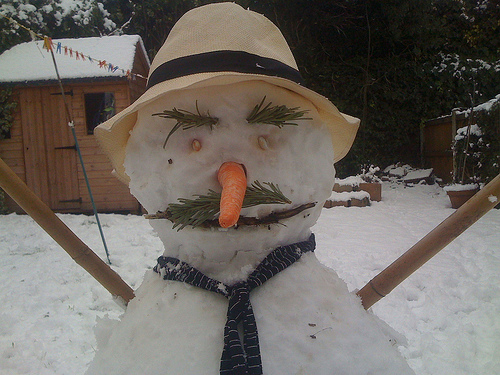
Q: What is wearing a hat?
A: Snowman.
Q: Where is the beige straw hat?
A: Atop the snowman.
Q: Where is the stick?
A: Right side of snowman.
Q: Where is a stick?
A: Left side of snowman.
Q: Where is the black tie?
A: On snowman.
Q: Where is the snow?
A: On building roof.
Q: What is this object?
A: Snowman.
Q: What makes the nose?
A: Carrot.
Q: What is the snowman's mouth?
A: A stick.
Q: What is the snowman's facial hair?
A: Pines.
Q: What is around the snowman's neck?
A: Tie.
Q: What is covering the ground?
A: Snow.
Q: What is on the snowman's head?
A: Hat.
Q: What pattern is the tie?
A: Striped.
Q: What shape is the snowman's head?
A: Round.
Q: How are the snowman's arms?
A: Up in the air.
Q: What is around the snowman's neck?
A: The tie.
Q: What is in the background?
A: The wood building.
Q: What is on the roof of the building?
A: The snow.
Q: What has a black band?
A: The white hat.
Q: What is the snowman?
A: Dressed up.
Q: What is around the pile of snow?
A: The blue tie.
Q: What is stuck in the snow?
A: The wooden pole.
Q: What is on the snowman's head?
A: The soft hat.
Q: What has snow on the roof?
A: Wooden cabin.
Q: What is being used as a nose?
A: Carrot.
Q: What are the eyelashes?
A: Grass.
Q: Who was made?
A: A snowman.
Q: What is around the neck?
A: Scarf.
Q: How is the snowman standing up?
A: Two sticks.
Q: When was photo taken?
A: Daytime.